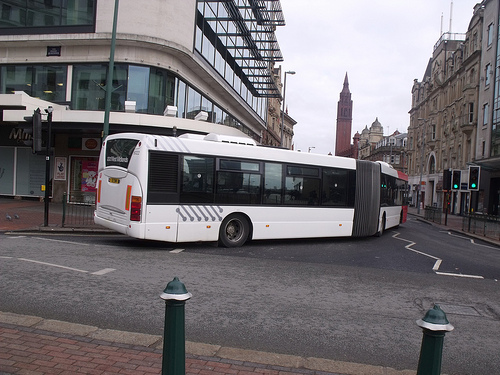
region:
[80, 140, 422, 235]
big white long bus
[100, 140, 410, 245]
big white and red bus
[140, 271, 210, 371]
green short pole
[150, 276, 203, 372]
green and silver short pole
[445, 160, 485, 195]
green traffic signal lights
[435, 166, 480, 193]
2 green traffic signal lights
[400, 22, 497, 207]
big tall nice building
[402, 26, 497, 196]
big brown tall building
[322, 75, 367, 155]
tall dark brown building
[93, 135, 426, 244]
red and white bus turning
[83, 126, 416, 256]
bus on a street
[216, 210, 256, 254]
rear wheel on a bus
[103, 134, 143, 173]
rear window on a bus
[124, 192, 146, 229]
rear tail light on a bus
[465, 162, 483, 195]
traffic signal on a pole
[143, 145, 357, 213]
side windows on a bus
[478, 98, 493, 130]
window on a building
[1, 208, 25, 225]
birds on a sidewalk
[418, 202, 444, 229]
fence near a street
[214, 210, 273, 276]
Black tire near back of bus.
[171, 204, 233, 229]
Gray markings on side of bus.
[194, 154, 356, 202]
Large windows on side of bus.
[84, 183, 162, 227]
Lights on back of bus.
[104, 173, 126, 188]
Yellow license plate on back of bus.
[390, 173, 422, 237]
Front of bus is red.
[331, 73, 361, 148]
Tall building in distance.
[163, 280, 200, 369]
Green post sticking out of bricks.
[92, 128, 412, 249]
White bus making a left turn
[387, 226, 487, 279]
White markings on the road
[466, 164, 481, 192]
A stoplight with a green light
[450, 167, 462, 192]
A stoplight with a green light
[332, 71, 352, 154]
Pointed skyscraper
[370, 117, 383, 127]
Dome roof on a building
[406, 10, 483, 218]
A building next to the road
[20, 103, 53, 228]
A stoplight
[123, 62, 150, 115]
A window on a building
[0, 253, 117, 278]
White markings on the road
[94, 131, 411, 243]
big black and white bus on street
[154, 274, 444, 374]
two short green poles on sidewalk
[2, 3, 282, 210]
big beige building in the corner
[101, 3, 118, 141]
large green pole on sidewalk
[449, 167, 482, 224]
traffic light with green light on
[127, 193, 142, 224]
small red back light of white bus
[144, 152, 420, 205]
black windows on right side of bus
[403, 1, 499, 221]
big building on right side of the street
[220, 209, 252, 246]
black back wheel of bus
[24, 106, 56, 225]
black traffic light on sidewalk behind white bus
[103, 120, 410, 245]
A large white bus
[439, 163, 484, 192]
Traffic lights displaying green lights.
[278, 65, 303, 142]
A street light.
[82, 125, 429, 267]
A bus going around a corner.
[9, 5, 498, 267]
Large buildings.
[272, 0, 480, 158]
The sky looks to be overcast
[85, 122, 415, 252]
A long white city bus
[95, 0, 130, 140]
A tall green pole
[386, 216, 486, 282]
A white zigzag line on the ground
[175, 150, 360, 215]
Side windows of a bus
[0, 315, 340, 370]
Bricks on the ground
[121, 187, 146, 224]
A red rear bus light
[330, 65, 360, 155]
A tall brown building